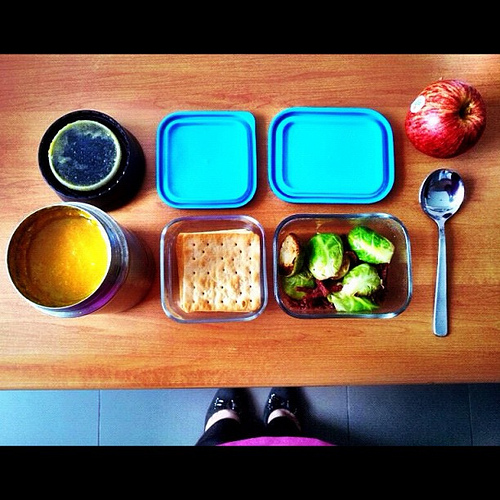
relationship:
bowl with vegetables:
[270, 210, 415, 321] [282, 225, 394, 310]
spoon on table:
[418, 169, 465, 339] [1, 47, 498, 392]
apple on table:
[403, 78, 487, 159] [1, 47, 498, 392]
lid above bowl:
[155, 111, 257, 207] [158, 213, 266, 325]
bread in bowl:
[175, 231, 262, 316] [158, 213, 269, 323]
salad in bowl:
[289, 229, 394, 309] [271, 210, 412, 321]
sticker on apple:
[408, 94, 427, 114] [371, 60, 491, 160]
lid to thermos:
[34, 106, 147, 211] [4, 200, 159, 318]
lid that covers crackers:
[151, 115, 263, 211] [174, 232, 254, 309]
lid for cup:
[31, 119, 123, 181] [23, 97, 139, 313]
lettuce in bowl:
[347, 224, 395, 264] [271, 210, 412, 321]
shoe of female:
[202, 386, 256, 428] [194, 385, 338, 447]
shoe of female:
[258, 386, 302, 427] [194, 385, 338, 446]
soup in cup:
[20, 218, 108, 308] [7, 202, 155, 319]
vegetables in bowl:
[278, 220, 439, 322] [270, 210, 415, 321]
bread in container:
[175, 229, 262, 314] [157, 211, 268, 333]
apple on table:
[406, 71, 476, 159] [1, 47, 498, 392]